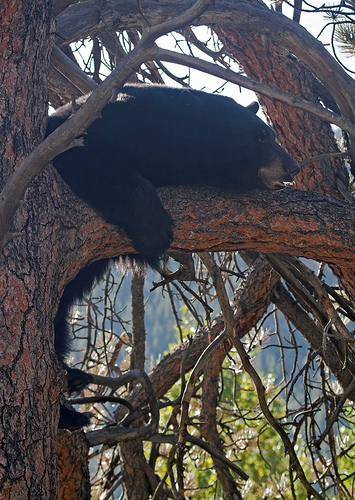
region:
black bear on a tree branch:
[35, 64, 306, 269]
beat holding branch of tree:
[30, 61, 308, 268]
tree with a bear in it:
[4, 4, 352, 439]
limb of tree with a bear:
[6, 79, 350, 287]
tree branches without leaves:
[227, 255, 350, 495]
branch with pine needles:
[318, 3, 354, 57]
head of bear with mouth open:
[187, 83, 304, 196]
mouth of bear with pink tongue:
[257, 163, 300, 197]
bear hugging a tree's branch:
[10, 63, 307, 280]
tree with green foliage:
[141, 296, 317, 498]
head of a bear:
[212, 91, 310, 193]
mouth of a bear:
[262, 162, 303, 193]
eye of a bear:
[246, 128, 282, 149]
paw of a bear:
[127, 198, 185, 265]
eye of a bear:
[252, 128, 271, 143]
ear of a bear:
[242, 87, 262, 115]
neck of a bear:
[150, 97, 229, 191]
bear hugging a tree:
[45, 77, 351, 282]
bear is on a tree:
[25, 72, 330, 446]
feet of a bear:
[53, 359, 111, 442]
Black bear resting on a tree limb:
[48, 85, 300, 258]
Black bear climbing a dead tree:
[45, 84, 299, 430]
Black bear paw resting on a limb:
[111, 173, 174, 257]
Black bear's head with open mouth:
[181, 90, 302, 189]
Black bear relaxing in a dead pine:
[23, 80, 300, 429]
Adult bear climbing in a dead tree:
[34, 84, 308, 429]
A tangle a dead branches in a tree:
[95, 263, 353, 486]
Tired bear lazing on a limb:
[1, 80, 301, 263]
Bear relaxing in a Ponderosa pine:
[4, 82, 301, 434]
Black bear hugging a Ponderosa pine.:
[0, 77, 303, 430]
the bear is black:
[31, 67, 306, 273]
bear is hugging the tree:
[52, 74, 323, 278]